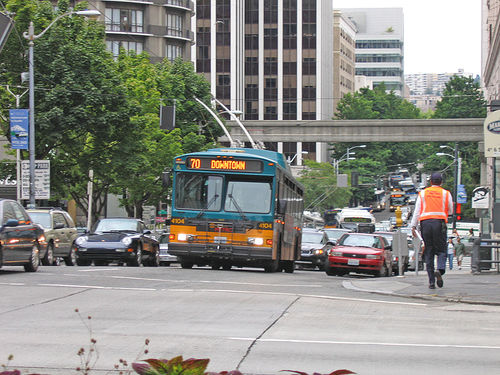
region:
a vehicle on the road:
[164, 137, 303, 277]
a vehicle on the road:
[76, 212, 160, 266]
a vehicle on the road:
[28, 205, 80, 267]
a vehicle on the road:
[0, 197, 46, 278]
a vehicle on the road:
[332, 225, 391, 282]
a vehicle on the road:
[291, 217, 329, 274]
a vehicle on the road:
[383, 188, 407, 212]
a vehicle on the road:
[365, 185, 384, 210]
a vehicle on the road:
[321, 216, 346, 244]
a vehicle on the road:
[397, 173, 416, 200]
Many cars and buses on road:
[146, 130, 401, 285]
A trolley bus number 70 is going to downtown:
[160, 87, 311, 272]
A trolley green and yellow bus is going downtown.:
[157, 92, 312, 267]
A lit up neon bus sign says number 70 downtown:
[173, 132, 280, 177]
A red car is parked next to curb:
[325, 226, 390, 270]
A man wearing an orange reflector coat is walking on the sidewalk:
[409, 170, 449, 285]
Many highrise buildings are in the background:
[89, 3, 371, 114]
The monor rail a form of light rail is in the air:
[221, 112, 484, 152]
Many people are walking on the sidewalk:
[411, 152, 474, 318]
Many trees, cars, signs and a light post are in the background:
[3, 0, 173, 265]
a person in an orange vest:
[400, 166, 460, 292]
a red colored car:
[324, 226, 396, 280]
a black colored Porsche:
[70, 211, 161, 272]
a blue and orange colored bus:
[168, 146, 300, 272]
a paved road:
[7, 276, 499, 367]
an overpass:
[214, 113, 492, 147]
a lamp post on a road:
[17, 6, 112, 208]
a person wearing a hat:
[407, 168, 457, 287]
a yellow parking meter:
[386, 206, 406, 288]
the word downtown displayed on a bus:
[204, 156, 250, 173]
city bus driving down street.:
[146, 124, 306, 270]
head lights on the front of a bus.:
[174, 205, 277, 257]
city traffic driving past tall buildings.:
[298, 110, 404, 356]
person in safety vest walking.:
[389, 170, 466, 327]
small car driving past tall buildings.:
[69, 196, 146, 283]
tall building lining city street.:
[191, 0, 361, 195]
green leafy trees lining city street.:
[27, 2, 171, 254]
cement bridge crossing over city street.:
[204, 101, 496, 175]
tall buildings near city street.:
[306, 1, 422, 112]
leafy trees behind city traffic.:
[286, 76, 483, 223]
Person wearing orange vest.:
[414, 191, 464, 261]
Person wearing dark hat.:
[398, 148, 459, 226]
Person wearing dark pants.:
[404, 225, 471, 292]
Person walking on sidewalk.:
[374, 154, 493, 221]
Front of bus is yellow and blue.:
[153, 155, 290, 302]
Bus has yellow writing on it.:
[185, 145, 280, 208]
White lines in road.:
[65, 221, 295, 347]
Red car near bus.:
[310, 222, 406, 322]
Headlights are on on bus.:
[175, 216, 318, 282]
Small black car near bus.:
[78, 206, 168, 302]